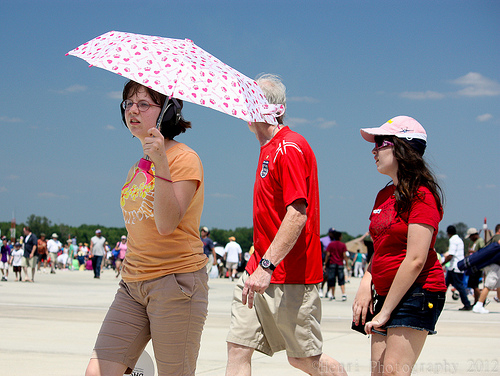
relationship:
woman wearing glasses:
[82, 80, 209, 375] [118, 100, 167, 116]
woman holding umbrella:
[56, 26, 303, 271] [65, 30, 276, 146]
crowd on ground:
[0, 225, 126, 280] [0, 262, 497, 372]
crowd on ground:
[199, 223, 254, 279] [0, 262, 497, 372]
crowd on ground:
[318, 230, 369, 300] [0, 262, 497, 372]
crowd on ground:
[439, 224, 498, 312] [0, 262, 497, 372]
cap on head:
[360, 112, 430, 147] [359, 112, 430, 178]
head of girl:
[359, 112, 430, 178] [352, 115, 450, 371]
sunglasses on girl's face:
[364, 134, 400, 156] [366, 137, 400, 173]